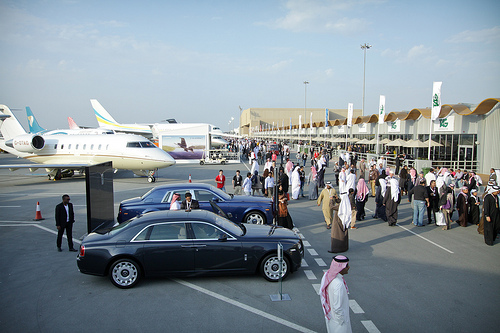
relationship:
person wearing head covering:
[318, 255, 350, 333] [320, 253, 346, 314]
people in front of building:
[217, 135, 499, 250] [226, 99, 499, 207]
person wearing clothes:
[318, 255, 350, 333] [319, 270, 352, 332]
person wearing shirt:
[215, 169, 227, 190] [216, 174, 226, 187]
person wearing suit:
[56, 194, 78, 251] [55, 202, 75, 248]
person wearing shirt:
[56, 194, 78, 251] [63, 204, 71, 221]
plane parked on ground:
[0, 105, 177, 183] [2, 163, 500, 331]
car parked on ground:
[78, 200, 306, 288] [2, 163, 500, 331]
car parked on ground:
[117, 183, 275, 227] [2, 163, 500, 331]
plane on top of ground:
[0, 105, 177, 183] [2, 163, 500, 331]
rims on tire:
[266, 258, 286, 278] [259, 252, 290, 282]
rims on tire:
[113, 262, 136, 286] [106, 256, 141, 289]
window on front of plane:
[126, 140, 141, 149] [0, 105, 177, 183]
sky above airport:
[0, 2, 499, 134] [0, 80, 499, 332]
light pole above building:
[357, 42, 372, 114] [226, 99, 499, 207]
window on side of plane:
[53, 143, 58, 150] [0, 105, 177, 183]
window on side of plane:
[60, 144, 65, 151] [0, 105, 177, 183]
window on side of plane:
[68, 143, 72, 149] [0, 105, 177, 183]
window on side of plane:
[82, 142, 87, 151] [0, 105, 177, 183]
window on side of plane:
[75, 142, 80, 150] [0, 105, 177, 183]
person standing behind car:
[182, 192, 199, 209] [78, 200, 306, 288]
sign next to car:
[271, 242, 291, 301] [78, 200, 306, 288]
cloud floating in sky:
[266, 1, 368, 37] [0, 2, 499, 134]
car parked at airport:
[78, 200, 306, 288] [0, 80, 499, 332]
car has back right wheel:
[78, 200, 306, 288] [107, 256, 141, 286]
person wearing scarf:
[480, 184, 500, 246] [487, 185, 500, 196]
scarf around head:
[487, 185, 500, 196] [487, 185, 499, 195]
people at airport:
[217, 135, 499, 250] [0, 80, 499, 332]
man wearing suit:
[56, 194, 78, 251] [55, 202, 75, 248]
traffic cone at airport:
[35, 201, 46, 223] [0, 80, 499, 332]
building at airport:
[226, 99, 499, 207] [0, 80, 499, 332]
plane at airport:
[0, 105, 177, 183] [0, 80, 499, 332]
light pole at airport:
[357, 42, 372, 114] [0, 80, 499, 332]